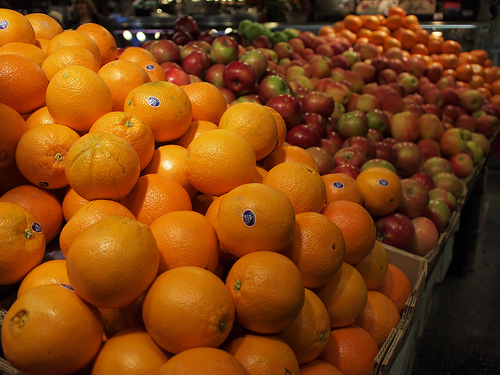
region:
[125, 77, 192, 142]
an orange with a sticker on it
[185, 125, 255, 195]
an orange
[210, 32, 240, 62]
a green and red apple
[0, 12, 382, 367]
a large stack of oranges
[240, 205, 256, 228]
the sticker is on an orange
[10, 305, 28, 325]
the butt of an orange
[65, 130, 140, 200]
the back of an orange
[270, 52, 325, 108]
a stack of apples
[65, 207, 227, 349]
three oranges grouped together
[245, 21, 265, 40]
this apple is green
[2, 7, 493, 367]
A bunch of fruit in a marketplace.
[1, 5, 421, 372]
A box of oranges.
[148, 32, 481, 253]
A box of apples.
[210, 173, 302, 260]
One orange with a sticker.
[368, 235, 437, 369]
A brown cardboard box.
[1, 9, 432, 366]
A cardboard box filled with oranges.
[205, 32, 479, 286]
A cardboard box filled with apples.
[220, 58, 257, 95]
One red apple.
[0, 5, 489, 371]
Apples and oranges next to each other.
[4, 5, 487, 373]
Apples and oranges in a fruit stand.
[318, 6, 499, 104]
Oranges in the furthest bin.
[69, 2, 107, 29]
A woman with long hair past the oranges.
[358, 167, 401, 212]
Large orange with blue sticker in the apple bin.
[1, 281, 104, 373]
A large orange closest to the camera in the bottom left corner.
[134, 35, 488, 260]
The closest green and red apples to the right of oranges.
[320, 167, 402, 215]
Two oranges in the bottom of the apple bin.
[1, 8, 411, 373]
The closest bin of oranges.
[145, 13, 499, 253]
All of the apples in the middle bins.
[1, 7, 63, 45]
The top two oranges in the closest bin.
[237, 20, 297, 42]
Five green apples to the top left of the furthest apple bin.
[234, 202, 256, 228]
Blue sticker on fruit.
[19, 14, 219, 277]
Big pile of oranges.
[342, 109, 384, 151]
Red and green apple.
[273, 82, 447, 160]
Pile of apples on table.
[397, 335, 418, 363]
White sticker on box.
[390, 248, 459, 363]
Big cardboard box with fruit.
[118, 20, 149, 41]
Glare of light across room.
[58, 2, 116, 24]
Woman walking by in the store.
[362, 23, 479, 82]
Bigger pile of navels.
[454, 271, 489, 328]
Dark slab of concrete.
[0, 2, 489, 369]
differents kind of fruits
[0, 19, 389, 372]
a lot odf oranges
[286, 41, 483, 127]
a lot of apples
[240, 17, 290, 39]
some green apples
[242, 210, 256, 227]
an illegible sticker on the orange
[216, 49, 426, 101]
apples in different positions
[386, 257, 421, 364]
part of a cartoon box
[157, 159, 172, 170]
the light reflected on an orange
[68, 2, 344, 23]
the background out of focus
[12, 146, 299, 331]
several juicy oranges